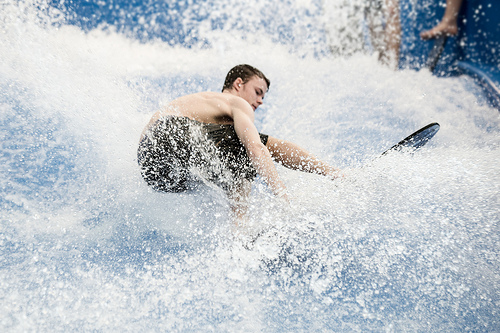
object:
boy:
[138, 62, 361, 256]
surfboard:
[242, 121, 442, 253]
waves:
[249, 135, 500, 266]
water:
[2, 1, 500, 332]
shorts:
[134, 114, 270, 196]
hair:
[221, 64, 271, 94]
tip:
[394, 122, 441, 153]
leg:
[199, 123, 345, 185]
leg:
[417, 0, 465, 40]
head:
[220, 63, 272, 113]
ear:
[232, 77, 242, 92]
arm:
[232, 96, 294, 206]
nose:
[256, 96, 263, 105]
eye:
[253, 87, 261, 96]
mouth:
[250, 103, 258, 112]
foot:
[418, 23, 458, 42]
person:
[418, 0, 464, 43]